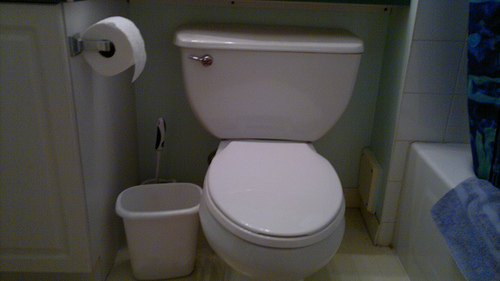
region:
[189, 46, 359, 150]
white tank on toilet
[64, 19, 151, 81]
white toilet roll on wall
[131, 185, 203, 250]
white bin next to toilet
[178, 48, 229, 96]
silver handle on toilet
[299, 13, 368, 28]
green wall behind toilet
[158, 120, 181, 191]
blue and white brush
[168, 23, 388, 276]
a white bathroom toilet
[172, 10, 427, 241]
a bathroom toilet is white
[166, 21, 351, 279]
a white toilet in bathroom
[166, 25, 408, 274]
a toilet in abthroom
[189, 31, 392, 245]
a toilet with seat down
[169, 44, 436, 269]
a toilet with lid down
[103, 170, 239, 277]
a white trash can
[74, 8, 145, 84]
a roll of toilet paper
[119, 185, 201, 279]
a white plastic garbage can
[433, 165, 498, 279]
a blue towel hanging over a bathtub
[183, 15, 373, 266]
a white toilet bowl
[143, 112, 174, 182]
a handle to a toilet brush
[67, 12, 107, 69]
a silver toilet paper holder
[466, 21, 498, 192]
a shower curtain with a pattern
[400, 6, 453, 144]
white tile wall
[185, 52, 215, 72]
silver handle on a toilet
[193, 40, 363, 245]
a toilet with the lid down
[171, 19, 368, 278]
A white porcelain commode.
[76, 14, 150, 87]
A toilet paper roll hung correctly.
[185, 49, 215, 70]
A toilet flush handle.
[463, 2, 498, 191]
A shower curtain in a bath.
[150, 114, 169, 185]
The handle of a toilet brush.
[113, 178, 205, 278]
A bathroom wastebasket.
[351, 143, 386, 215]
A plumbing access cover near a bathtub.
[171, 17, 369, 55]
The lid of a toilet tank.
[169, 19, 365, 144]
The tank of a commode.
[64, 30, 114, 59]
A toilet paper holder bracket.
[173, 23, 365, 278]
the white toilet bowl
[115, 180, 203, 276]
the small white trash can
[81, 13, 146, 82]
the roll of toilet paper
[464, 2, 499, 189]
the colorful shower curtain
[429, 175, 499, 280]
the folded blue towel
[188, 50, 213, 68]
the silver flush handle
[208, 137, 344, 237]
the white toilet seat cover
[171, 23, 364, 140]
the cover for the tank on the toilet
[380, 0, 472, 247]
the tiles on the wall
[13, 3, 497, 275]
a bathroom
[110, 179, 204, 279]
a trash bin in bathroom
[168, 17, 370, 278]
a toilet in the bathroom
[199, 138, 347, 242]
a lid of the toilet seat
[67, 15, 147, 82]
toilet paper hangs on the wall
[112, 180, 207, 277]
garbage can is empty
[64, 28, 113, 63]
toilet roll dispensor is metal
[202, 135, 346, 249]
toilet seat is down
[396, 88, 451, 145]
A tile in a wall.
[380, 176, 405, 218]
A tile in a wall.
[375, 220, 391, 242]
A tile in a wall.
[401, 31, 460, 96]
A tile in a wall.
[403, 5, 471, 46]
A tile in a wall.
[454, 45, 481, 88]
A tile in a wall.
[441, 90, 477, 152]
A tile in a wall.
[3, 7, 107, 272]
A door for a cabinet.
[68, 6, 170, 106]
Roll of toilet paper.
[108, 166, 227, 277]
A white trash can.